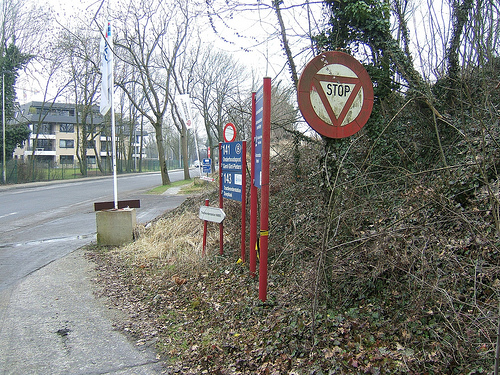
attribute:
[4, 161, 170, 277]
road — clear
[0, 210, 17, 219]
marking — lane, white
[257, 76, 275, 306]
pole — iron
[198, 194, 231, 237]
board — direction indicator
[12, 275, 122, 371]
sidewalk — the cement sidewalk 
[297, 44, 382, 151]
stop sign — red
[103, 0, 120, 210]
pole — white, iron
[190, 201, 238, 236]
sign — small, white, pointing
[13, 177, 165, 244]
road — dusty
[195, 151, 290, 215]
board — blue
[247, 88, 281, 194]
sign — blue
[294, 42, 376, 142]
sign — stop, round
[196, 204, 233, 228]
board — small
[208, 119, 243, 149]
red sign — small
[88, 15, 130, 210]
pole — long, electric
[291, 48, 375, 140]
sign — circle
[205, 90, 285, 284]
board — pictured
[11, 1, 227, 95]
trees — leafless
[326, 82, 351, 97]
word — stop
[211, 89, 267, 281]
boards — group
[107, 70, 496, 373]
grass — green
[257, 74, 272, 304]
pole — red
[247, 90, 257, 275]
pole — red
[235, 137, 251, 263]
pole — red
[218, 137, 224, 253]
pole — red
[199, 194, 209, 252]
pole — red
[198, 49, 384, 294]
signs — several